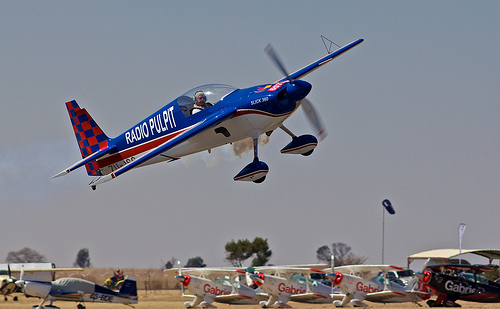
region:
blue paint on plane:
[246, 160, 268, 168]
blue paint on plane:
[85, 133, 95, 135]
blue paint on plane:
[283, 88, 308, 94]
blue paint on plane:
[286, 136, 313, 141]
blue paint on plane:
[141, 141, 176, 159]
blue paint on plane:
[245, 88, 257, 101]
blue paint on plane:
[173, 108, 183, 119]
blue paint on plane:
[306, 53, 339, 71]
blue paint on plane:
[111, 141, 128, 146]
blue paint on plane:
[163, 108, 182, 115]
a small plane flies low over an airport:
[0, 35, 499, 305]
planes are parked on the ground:
[156, 247, 498, 307]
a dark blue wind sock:
[379, 193, 397, 263]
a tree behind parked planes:
[176, 233, 311, 305]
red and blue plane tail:
[61, 95, 113, 175]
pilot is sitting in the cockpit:
[173, 80, 237, 118]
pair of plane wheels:
[229, 132, 321, 186]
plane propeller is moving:
[261, 40, 334, 143]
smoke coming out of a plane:
[215, 120, 278, 160]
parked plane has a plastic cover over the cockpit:
[12, 260, 144, 307]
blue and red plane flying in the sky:
[40, 14, 402, 204]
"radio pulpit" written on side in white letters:
[119, 98, 178, 152]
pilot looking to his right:
[187, 84, 219, 116]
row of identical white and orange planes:
[152, 249, 415, 307]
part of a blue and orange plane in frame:
[410, 254, 497, 307]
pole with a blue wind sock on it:
[374, 180, 400, 265]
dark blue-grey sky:
[0, 0, 495, 273]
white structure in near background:
[0, 258, 92, 283]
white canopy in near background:
[399, 221, 497, 273]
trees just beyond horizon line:
[0, 240, 376, 273]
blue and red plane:
[25, 12, 350, 192]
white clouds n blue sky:
[421, 53, 496, 123]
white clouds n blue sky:
[378, 152, 400, 166]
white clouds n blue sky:
[392, 126, 436, 177]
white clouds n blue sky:
[148, 198, 192, 235]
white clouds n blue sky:
[38, 209, 99, 239]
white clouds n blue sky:
[67, 48, 118, 69]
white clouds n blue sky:
[151, 31, 226, 78]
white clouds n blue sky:
[55, 12, 145, 44]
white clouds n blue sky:
[18, 53, 63, 91]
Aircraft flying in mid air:
[47, 33, 373, 195]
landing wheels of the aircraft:
[229, 120, 321, 189]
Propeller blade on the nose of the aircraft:
[262, 40, 292, 85]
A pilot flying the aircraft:
[190, 88, 217, 115]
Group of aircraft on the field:
[157, 243, 499, 307]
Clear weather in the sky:
[0, 1, 498, 265]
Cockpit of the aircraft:
[170, 81, 240, 119]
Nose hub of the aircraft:
[284, 78, 314, 101]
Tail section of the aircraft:
[45, 95, 119, 180]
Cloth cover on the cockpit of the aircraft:
[49, 276, 95, 294]